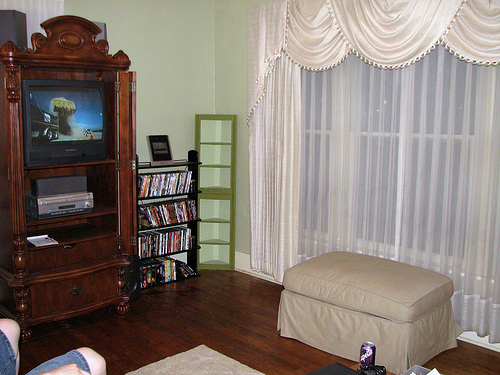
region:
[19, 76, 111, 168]
A black color television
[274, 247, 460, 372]
A beige ottoman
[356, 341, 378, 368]
A purple and white can of soda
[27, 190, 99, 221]
A television sound tuner for surrond sound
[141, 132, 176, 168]
A framed picture on a shelf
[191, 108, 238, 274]
A green empty rack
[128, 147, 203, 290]
A DVD movie rack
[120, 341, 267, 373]
Part of a beige rug on the floor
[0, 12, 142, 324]
A wooden entertainment center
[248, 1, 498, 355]
Off white colored drapes and curtains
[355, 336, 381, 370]
Can on table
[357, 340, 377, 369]
Can is on table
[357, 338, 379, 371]
Can on corner of table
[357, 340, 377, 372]
Can is on corner of table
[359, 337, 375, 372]
Purple can on table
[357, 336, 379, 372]
Purple can is on table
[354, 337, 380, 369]
Purple can on corner of table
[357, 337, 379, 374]
Purple can is on corner of table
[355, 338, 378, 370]
Aluminum can on corner of table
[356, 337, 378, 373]
Aluminum can is on corner of table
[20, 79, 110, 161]
black television in the cabinet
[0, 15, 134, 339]
tall, wooden entertainment cabinet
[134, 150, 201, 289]
black shelves that hold DVDs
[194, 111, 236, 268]
empty green shelves in the corner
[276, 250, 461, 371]
ivory colored ottoman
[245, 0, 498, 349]
large white curtains over the window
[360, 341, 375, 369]
purple can of soda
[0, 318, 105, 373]
legs of a person watching tv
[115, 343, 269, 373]
white rug on the floor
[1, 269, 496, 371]
wooden floor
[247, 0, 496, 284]
white curtain over a vertical blind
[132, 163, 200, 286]
dvd case filled with dvd's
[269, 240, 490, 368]
Beige colored ottoman on the floor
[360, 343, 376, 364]
grape crush soda can on table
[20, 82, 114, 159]
19 inch tv in a stand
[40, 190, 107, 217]
dvd player on a shelf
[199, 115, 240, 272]
green corner plant stand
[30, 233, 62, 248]
instruction book for the dvd player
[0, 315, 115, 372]
persons kneess while they are sitting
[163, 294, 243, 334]
brown shiny hardwood floor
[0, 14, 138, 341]
an entertainment center for tv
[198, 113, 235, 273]
a corner shelf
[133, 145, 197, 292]
a shelf for games and movies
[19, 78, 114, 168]
tv in the entertainment center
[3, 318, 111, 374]
a persons legs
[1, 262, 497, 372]
a hardwood floor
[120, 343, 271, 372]
a rug in the middle of the room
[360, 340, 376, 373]
a canned beverage on a table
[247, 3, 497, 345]
a window behind the curtains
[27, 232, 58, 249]
a netflix rental